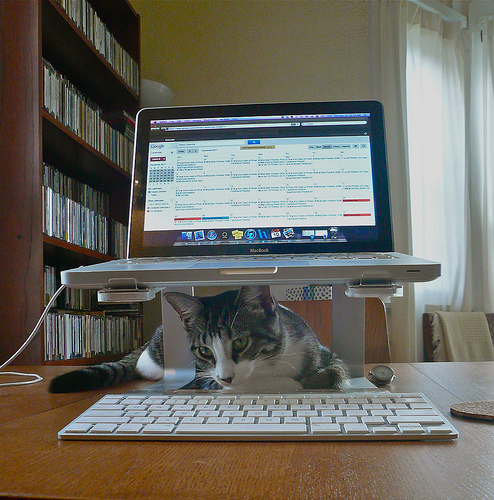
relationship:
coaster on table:
[447, 380, 492, 439] [15, 352, 492, 481]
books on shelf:
[47, 315, 142, 360] [40, 78, 131, 176]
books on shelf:
[49, 71, 53, 112] [40, 78, 131, 176]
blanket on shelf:
[424, 305, 494, 363] [40, 78, 131, 176]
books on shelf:
[111, 127, 113, 161] [40, 78, 131, 176]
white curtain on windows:
[398, 49, 493, 208] [379, 5, 492, 360]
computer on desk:
[136, 84, 423, 295] [32, 223, 437, 422]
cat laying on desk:
[46, 281, 346, 394] [0, 358, 493, 498]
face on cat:
[160, 287, 284, 394] [46, 281, 354, 395]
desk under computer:
[0, 358, 493, 498] [56, 99, 458, 441]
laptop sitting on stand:
[57, 98, 440, 287] [96, 268, 407, 391]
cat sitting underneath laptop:
[46, 281, 354, 395] [57, 98, 440, 287]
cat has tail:
[46, 281, 354, 395] [44, 338, 155, 395]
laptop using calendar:
[57, 98, 440, 287] [148, 143, 378, 227]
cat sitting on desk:
[46, 281, 346, 394] [0, 358, 493, 498]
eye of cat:
[225, 335, 253, 351] [46, 281, 354, 395]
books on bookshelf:
[60, 23, 142, 93] [1, 2, 143, 367]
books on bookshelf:
[38, 60, 137, 175] [1, 2, 143, 367]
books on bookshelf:
[45, 160, 131, 261] [1, 2, 143, 367]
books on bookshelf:
[47, 315, 142, 360] [1, 2, 143, 367]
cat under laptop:
[46, 281, 346, 394] [57, 98, 440, 287]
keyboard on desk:
[56, 389, 465, 444] [0, 358, 493, 498]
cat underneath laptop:
[46, 281, 354, 395] [57, 98, 440, 287]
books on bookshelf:
[39, 57, 132, 167] [0, 0, 158, 371]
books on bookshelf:
[47, 315, 142, 360] [0, 0, 158, 371]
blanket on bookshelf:
[424, 305, 494, 363] [0, 0, 158, 371]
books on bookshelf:
[60, 23, 142, 93] [0, 0, 158, 371]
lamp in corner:
[137, 71, 175, 110] [139, 9, 170, 106]